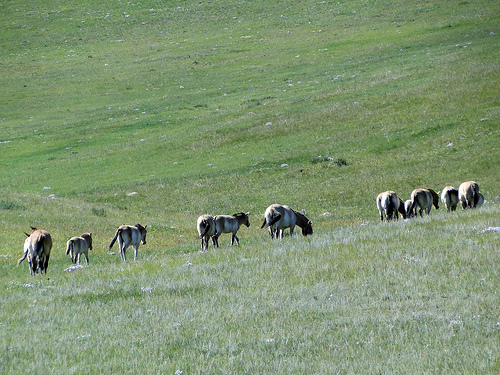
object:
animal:
[197, 214, 218, 251]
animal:
[261, 204, 314, 241]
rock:
[264, 121, 273, 127]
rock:
[446, 142, 455, 148]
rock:
[279, 163, 289, 170]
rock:
[178, 85, 184, 90]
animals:
[65, 233, 93, 266]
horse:
[404, 188, 439, 218]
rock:
[126, 191, 139, 197]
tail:
[109, 228, 119, 253]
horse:
[16, 225, 52, 277]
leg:
[131, 246, 138, 257]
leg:
[231, 230, 236, 242]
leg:
[72, 252, 79, 262]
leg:
[288, 224, 295, 235]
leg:
[121, 240, 131, 258]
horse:
[376, 190, 406, 221]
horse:
[261, 203, 314, 240]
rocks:
[117, 103, 150, 119]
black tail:
[388, 194, 393, 221]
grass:
[1, 0, 500, 375]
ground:
[1, 0, 500, 375]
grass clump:
[335, 157, 348, 167]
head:
[242, 212, 250, 228]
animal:
[65, 232, 93, 265]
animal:
[210, 212, 250, 248]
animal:
[458, 181, 480, 210]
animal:
[441, 185, 459, 212]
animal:
[110, 223, 149, 261]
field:
[0, 0, 499, 375]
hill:
[0, 0, 500, 375]